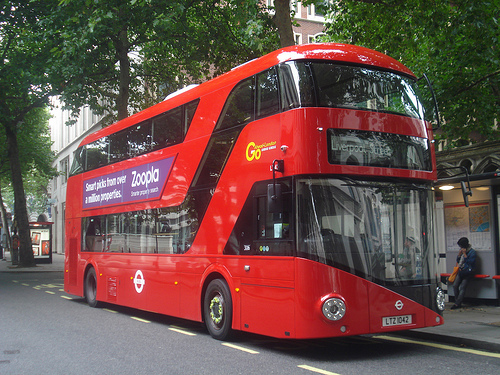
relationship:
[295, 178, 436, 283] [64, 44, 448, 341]
windshield on bus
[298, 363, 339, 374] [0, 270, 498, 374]
line on street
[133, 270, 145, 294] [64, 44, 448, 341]
brand on bus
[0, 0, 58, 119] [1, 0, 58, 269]
leaves on tree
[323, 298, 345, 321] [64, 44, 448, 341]
headlight on bus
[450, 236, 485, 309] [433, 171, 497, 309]
person at a bus stop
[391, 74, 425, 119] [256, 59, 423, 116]
reflection on front window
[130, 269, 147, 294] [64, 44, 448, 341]
brand of bus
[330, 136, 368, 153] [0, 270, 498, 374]
name of street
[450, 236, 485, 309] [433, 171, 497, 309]
person sitting on bus stop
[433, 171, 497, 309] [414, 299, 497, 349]
bus stop on walkway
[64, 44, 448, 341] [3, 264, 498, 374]
bus in foreground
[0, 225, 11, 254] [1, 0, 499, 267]
person in background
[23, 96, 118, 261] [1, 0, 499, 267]
building in background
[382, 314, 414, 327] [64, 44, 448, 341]
plate of bus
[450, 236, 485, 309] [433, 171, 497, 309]
person sitting in bus stop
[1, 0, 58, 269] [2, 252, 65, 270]
tree on walkway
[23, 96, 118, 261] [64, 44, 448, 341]
building behind bus